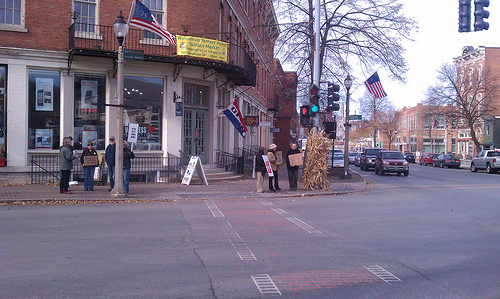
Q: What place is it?
A: It is a street.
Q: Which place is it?
A: It is a street.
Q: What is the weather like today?
A: It is clear.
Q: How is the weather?
A: It is clear.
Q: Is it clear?
A: Yes, it is clear.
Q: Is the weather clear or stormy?
A: It is clear.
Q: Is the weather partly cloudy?
A: No, it is clear.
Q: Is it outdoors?
A: Yes, it is outdoors.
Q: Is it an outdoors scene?
A: Yes, it is outdoors.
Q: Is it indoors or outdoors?
A: It is outdoors.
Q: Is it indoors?
A: No, it is outdoors.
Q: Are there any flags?
A: Yes, there is a flag.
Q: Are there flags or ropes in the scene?
A: Yes, there is a flag.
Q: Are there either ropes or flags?
A: Yes, there is a flag.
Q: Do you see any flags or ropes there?
A: Yes, there is a flag.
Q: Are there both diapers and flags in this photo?
A: No, there is a flag but no diapers.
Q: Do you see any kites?
A: No, there are no kites.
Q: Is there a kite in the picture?
A: No, there are no kites.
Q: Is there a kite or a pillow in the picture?
A: No, there are no kites or pillows.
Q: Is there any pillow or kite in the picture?
A: No, there are no kites or pillows.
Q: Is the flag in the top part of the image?
A: Yes, the flag is in the top of the image.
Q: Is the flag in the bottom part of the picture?
A: No, the flag is in the top of the image.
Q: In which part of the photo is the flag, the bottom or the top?
A: The flag is in the top of the image.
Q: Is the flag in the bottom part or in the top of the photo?
A: The flag is in the top of the image.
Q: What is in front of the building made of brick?
A: The flag is in front of the building.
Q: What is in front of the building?
A: The flag is in front of the building.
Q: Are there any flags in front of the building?
A: Yes, there is a flag in front of the building.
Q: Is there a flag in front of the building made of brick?
A: Yes, there is a flag in front of the building.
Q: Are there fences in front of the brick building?
A: No, there is a flag in front of the building.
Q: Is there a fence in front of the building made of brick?
A: No, there is a flag in front of the building.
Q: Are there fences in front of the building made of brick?
A: No, there is a flag in front of the building.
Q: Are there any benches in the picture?
A: No, there are no benches.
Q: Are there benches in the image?
A: No, there are no benches.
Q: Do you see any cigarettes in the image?
A: No, there are no cigarettes.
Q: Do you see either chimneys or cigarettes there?
A: No, there are no cigarettes or chimneys.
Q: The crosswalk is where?
A: The crosswalk is on the street.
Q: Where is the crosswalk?
A: The crosswalk is on the street.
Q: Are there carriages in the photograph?
A: No, there are no carriages.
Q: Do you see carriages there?
A: No, there are no carriages.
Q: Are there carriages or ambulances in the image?
A: No, there are no carriages or ambulances.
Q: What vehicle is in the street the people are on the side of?
A: The vehicle is a car.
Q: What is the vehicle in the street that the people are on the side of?
A: The vehicle is a car.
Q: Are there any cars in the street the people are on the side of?
A: Yes, there is a car in the street.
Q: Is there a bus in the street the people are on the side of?
A: No, there is a car in the street.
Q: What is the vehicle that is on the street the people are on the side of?
A: The vehicle is a car.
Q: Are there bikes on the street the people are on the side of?
A: No, there is a car on the street.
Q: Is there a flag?
A: Yes, there is a flag.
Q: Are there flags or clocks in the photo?
A: Yes, there is a flag.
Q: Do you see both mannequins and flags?
A: No, there is a flag but no mannequins.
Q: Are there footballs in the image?
A: No, there are no footballs.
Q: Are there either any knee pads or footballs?
A: No, there are no footballs or knee pads.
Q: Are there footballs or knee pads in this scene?
A: No, there are no footballs or knee pads.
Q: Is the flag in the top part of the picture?
A: Yes, the flag is in the top of the image.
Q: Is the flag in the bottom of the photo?
A: No, the flag is in the top of the image.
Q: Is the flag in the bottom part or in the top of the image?
A: The flag is in the top of the image.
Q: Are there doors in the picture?
A: Yes, there are doors.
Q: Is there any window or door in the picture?
A: Yes, there are doors.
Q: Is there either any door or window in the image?
A: Yes, there are doors.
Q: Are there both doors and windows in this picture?
A: Yes, there are both doors and a window.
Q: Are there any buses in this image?
A: No, there are no buses.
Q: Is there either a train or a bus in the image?
A: No, there are no buses or trains.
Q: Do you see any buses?
A: No, there are no buses.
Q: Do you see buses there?
A: No, there are no buses.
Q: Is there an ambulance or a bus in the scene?
A: No, there are no buses or ambulances.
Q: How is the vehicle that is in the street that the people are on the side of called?
A: The vehicle is a car.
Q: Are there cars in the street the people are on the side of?
A: Yes, there is a car in the street.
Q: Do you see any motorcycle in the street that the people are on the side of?
A: No, there is a car in the street.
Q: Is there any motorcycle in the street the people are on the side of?
A: No, there is a car in the street.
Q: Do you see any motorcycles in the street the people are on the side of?
A: No, there is a car in the street.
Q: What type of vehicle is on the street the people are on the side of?
A: The vehicle is a car.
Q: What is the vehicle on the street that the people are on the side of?
A: The vehicle is a car.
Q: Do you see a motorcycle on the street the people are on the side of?
A: No, there is a car on the street.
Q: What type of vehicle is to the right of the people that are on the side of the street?
A: The vehicle is a car.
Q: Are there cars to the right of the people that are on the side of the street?
A: Yes, there is a car to the right of the people.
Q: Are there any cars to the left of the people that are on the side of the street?
A: No, the car is to the right of the people.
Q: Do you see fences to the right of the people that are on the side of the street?
A: No, there is a car to the right of the people.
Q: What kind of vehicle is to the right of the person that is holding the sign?
A: The vehicle is a car.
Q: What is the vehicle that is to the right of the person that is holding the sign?
A: The vehicle is a car.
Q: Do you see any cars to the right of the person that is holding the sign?
A: Yes, there is a car to the right of the person.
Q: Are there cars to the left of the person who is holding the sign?
A: No, the car is to the right of the person.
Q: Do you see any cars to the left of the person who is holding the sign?
A: No, the car is to the right of the person.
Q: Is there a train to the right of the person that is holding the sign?
A: No, there is a car to the right of the person.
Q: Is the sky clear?
A: Yes, the sky is clear.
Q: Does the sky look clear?
A: Yes, the sky is clear.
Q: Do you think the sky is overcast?
A: No, the sky is clear.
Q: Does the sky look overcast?
A: No, the sky is clear.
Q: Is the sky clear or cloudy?
A: The sky is clear.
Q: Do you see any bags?
A: No, there are no bags.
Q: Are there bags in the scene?
A: No, there are no bags.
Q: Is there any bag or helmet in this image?
A: No, there are no bags or helmets.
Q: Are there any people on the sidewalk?
A: Yes, there is a person on the sidewalk.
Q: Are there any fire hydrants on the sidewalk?
A: No, there is a person on the sidewalk.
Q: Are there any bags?
A: No, there are no bags.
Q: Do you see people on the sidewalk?
A: Yes, there is a person on the sidewalk.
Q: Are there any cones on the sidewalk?
A: No, there is a person on the sidewalk.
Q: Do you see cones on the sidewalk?
A: No, there is a person on the sidewalk.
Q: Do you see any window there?
A: Yes, there is a window.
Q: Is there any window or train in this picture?
A: Yes, there is a window.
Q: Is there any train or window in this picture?
A: Yes, there is a window.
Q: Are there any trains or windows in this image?
A: Yes, there is a window.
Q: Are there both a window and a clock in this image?
A: No, there is a window but no clocks.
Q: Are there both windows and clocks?
A: No, there is a window but no clocks.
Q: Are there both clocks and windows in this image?
A: No, there is a window but no clocks.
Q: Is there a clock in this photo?
A: No, there are no clocks.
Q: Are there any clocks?
A: No, there are no clocks.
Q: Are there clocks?
A: No, there are no clocks.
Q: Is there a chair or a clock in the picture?
A: No, there are no clocks or chairs.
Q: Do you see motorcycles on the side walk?
A: No, there is a person on the side walk.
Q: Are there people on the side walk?
A: Yes, there is a person on the side walk.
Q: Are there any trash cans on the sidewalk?
A: No, there is a person on the sidewalk.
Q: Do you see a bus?
A: No, there are no buses.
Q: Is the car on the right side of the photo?
A: Yes, the car is on the right of the image.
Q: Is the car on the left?
A: No, the car is on the right of the image.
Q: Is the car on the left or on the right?
A: The car is on the right of the image.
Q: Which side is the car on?
A: The car is on the right of the image.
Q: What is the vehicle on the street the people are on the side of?
A: The vehicle is a car.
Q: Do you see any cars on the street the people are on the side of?
A: Yes, there is a car on the street.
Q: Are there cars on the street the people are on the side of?
A: Yes, there is a car on the street.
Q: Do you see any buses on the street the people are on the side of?
A: No, there is a car on the street.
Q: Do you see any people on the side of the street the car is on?
A: Yes, there are people on the side of the street.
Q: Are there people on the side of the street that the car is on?
A: Yes, there are people on the side of the street.